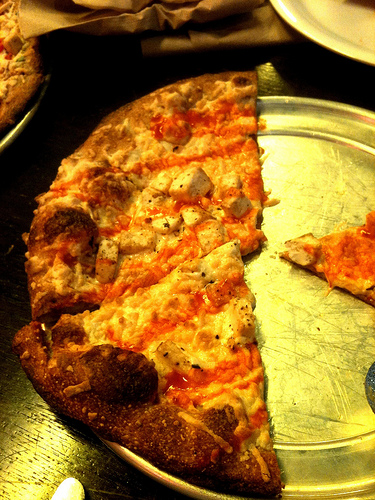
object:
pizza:
[11, 68, 374, 496]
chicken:
[169, 163, 213, 205]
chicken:
[202, 241, 244, 280]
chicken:
[94, 237, 121, 286]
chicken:
[233, 299, 256, 337]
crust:
[12, 322, 281, 497]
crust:
[24, 65, 260, 320]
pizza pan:
[274, 0, 374, 67]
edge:
[270, 1, 375, 67]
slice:
[280, 211, 375, 306]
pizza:
[0, 4, 43, 119]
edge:
[0, 89, 47, 152]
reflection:
[277, 0, 298, 27]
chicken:
[220, 187, 250, 219]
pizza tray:
[82, 93, 375, 498]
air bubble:
[89, 348, 158, 404]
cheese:
[28, 69, 265, 322]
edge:
[258, 93, 374, 124]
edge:
[108, 440, 375, 499]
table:
[0, 0, 375, 500]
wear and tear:
[0, 394, 132, 498]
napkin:
[18, 0, 267, 40]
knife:
[49, 475, 87, 500]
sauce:
[150, 108, 263, 146]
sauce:
[161, 369, 234, 395]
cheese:
[62, 358, 91, 409]